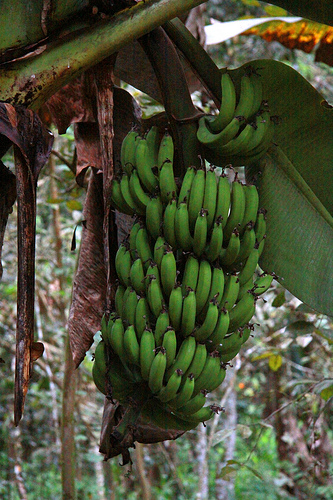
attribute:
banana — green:
[194, 213, 207, 254]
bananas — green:
[94, 67, 277, 423]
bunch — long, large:
[94, 67, 273, 454]